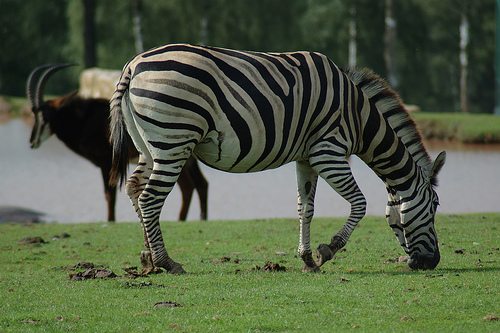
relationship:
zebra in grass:
[107, 44, 446, 276] [3, 214, 498, 331]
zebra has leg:
[107, 44, 446, 276] [295, 162, 323, 272]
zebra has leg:
[107, 44, 446, 276] [308, 146, 369, 268]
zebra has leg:
[107, 44, 446, 276] [137, 158, 187, 276]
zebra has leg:
[107, 44, 446, 276] [127, 159, 165, 276]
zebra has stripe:
[107, 44, 446, 276] [151, 167, 181, 178]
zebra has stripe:
[107, 44, 446, 276] [148, 178, 178, 190]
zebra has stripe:
[107, 44, 446, 276] [154, 155, 192, 166]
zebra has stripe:
[107, 44, 446, 276] [149, 135, 200, 150]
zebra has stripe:
[107, 44, 446, 276] [128, 105, 204, 138]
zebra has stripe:
[107, 44, 446, 276] [127, 83, 218, 135]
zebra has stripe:
[107, 44, 446, 276] [135, 59, 252, 173]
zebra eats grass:
[107, 44, 446, 276] [3, 214, 498, 331]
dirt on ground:
[62, 257, 117, 284] [7, 225, 497, 331]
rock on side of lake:
[74, 69, 116, 91] [2, 111, 498, 229]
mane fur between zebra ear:
[341, 61, 438, 185] [427, 143, 449, 196]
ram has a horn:
[15, 73, 242, 244] [36, 63, 76, 106]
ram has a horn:
[15, 73, 242, 244] [17, 55, 42, 105]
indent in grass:
[152, 300, 180, 311] [3, 214, 498, 331]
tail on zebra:
[108, 72, 129, 184] [107, 44, 446, 276]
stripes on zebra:
[209, 57, 294, 127] [91, 40, 481, 300]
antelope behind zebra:
[21, 59, 211, 221] [107, 44, 446, 276]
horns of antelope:
[9, 45, 96, 137] [27, 51, 87, 153]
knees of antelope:
[169, 158, 213, 227] [18, 58, 230, 220]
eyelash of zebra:
[428, 166, 446, 225] [91, 40, 481, 300]